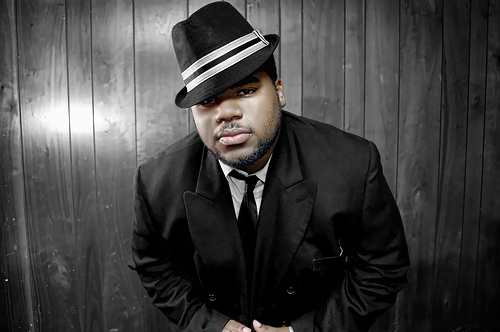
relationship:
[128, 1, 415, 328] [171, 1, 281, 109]
man wearing cap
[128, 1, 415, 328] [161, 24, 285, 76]
man wearing cap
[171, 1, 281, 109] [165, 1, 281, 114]
cap in cap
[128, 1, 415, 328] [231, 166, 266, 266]
man wearing tie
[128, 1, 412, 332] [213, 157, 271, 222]
man wearing shirt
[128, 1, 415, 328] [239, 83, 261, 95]
man has eye